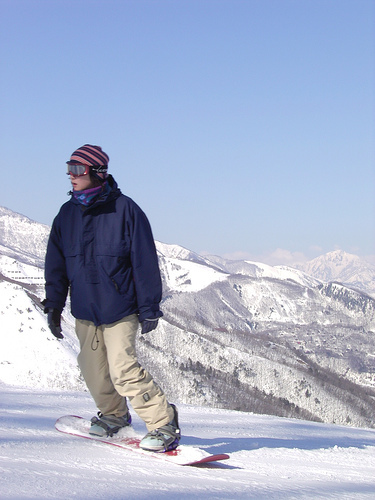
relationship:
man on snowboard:
[36, 139, 188, 449] [61, 412, 232, 465]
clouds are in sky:
[188, 197, 337, 239] [171, 12, 368, 238]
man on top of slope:
[43, 143, 182, 451] [0, 384, 373, 496]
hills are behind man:
[8, 205, 281, 385] [43, 143, 182, 451]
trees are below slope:
[195, 364, 301, 417] [0, 384, 373, 496]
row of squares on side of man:
[4, 267, 53, 293] [36, 139, 188, 449]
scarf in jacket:
[69, 184, 111, 205] [45, 174, 165, 321]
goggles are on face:
[65, 161, 99, 178] [71, 160, 89, 188]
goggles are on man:
[65, 161, 99, 178] [36, 139, 188, 449]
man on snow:
[36, 139, 188, 449] [65, 456, 329, 496]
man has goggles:
[36, 139, 188, 449] [65, 161, 99, 178]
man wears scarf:
[36, 139, 188, 449] [69, 184, 111, 205]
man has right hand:
[36, 139, 188, 449] [37, 306, 72, 352]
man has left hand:
[36, 139, 188, 449] [136, 310, 165, 332]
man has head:
[36, 139, 188, 449] [61, 144, 117, 193]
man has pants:
[36, 139, 188, 449] [66, 315, 184, 431]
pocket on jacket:
[91, 232, 133, 275] [45, 174, 165, 321]